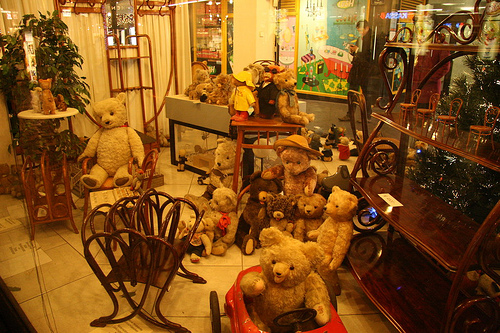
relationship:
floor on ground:
[6, 143, 408, 333] [17, 278, 97, 321]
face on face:
[262, 243, 310, 287] [262, 240, 305, 282]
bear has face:
[237, 229, 333, 329] [262, 240, 305, 282]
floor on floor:
[6, 143, 408, 333] [6, 143, 383, 331]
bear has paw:
[80, 97, 144, 187] [84, 175, 99, 190]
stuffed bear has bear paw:
[236, 223, 332, 326] [248, 277, 267, 296]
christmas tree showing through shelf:
[409, 50, 500, 222] [343, 10, 499, 333]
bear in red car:
[237, 229, 330, 333] [222, 257, 350, 330]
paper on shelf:
[376, 190, 401, 205] [345, 169, 492, 271]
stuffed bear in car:
[236, 223, 332, 326] [197, 254, 349, 330]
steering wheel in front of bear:
[268, 306, 317, 331] [213, 240, 357, 317]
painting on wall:
[291, 0, 356, 100] [274, 5, 302, 101]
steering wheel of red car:
[274, 307, 318, 327] [205, 263, 351, 333]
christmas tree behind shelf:
[409, 50, 484, 200] [332, 22, 499, 331]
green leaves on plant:
[42, 42, 92, 119] [12, 5, 106, 116]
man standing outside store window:
[337, 25, 381, 125] [263, 5, 399, 146]